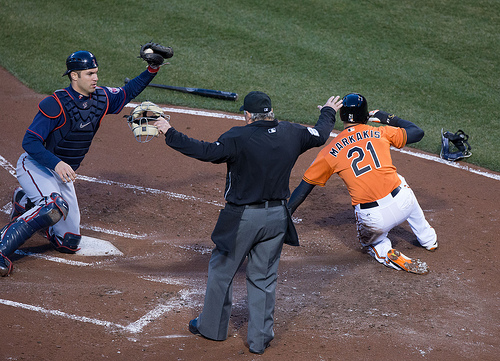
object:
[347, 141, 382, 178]
number 21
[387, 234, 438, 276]
shoe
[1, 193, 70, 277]
leg pad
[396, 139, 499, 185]
line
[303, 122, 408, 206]
jersey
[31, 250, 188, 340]
markings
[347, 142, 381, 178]
black numbers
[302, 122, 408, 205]
shirt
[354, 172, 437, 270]
pants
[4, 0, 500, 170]
grass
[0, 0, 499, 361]
field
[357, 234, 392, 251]
man's knee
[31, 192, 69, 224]
man's knee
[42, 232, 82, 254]
man's knee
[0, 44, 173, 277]
cather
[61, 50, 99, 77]
helmet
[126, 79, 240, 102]
baseballbat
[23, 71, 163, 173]
uniform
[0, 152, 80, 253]
pants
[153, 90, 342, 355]
man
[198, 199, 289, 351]
pants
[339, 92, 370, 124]
helmet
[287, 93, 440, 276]
baseball runner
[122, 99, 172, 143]
facemask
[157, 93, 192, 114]
wall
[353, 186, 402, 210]
belt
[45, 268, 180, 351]
floor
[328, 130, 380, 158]
letters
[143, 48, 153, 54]
ball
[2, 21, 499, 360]
ground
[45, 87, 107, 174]
nike vest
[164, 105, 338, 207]
shirt